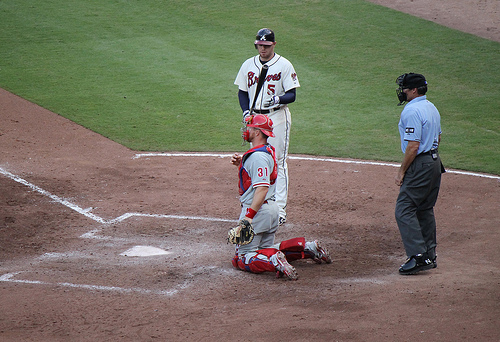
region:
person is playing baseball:
[226, 23, 305, 127]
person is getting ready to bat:
[241, 17, 301, 122]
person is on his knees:
[222, 110, 313, 282]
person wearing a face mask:
[241, 116, 263, 140]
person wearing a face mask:
[383, 62, 413, 105]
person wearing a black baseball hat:
[253, 27, 280, 51]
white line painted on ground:
[8, 153, 121, 228]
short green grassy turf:
[123, 66, 178, 106]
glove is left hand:
[233, 197, 256, 247]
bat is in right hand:
[240, 58, 264, 126]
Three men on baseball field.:
[222, 23, 454, 283]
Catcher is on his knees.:
[221, 108, 333, 285]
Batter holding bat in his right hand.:
[231, 20, 303, 112]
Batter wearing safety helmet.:
[250, 25, 283, 55]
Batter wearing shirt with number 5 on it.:
[228, 26, 303, 111]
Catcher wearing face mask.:
[236, 112, 278, 143]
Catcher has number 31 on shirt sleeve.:
[233, 111, 278, 224]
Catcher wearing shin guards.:
[222, 108, 324, 280]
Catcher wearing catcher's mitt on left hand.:
[224, 107, 306, 244]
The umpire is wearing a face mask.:
[383, 67, 445, 160]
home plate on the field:
[118, 236, 176, 261]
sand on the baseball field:
[20, 152, 430, 337]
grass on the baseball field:
[7, 0, 482, 170]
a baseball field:
[5, 1, 490, 331]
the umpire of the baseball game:
[387, 67, 437, 268]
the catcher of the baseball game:
[225, 107, 305, 277]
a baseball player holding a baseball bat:
[246, 25, 291, 155]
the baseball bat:
[247, 65, 272, 110]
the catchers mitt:
[227, 218, 259, 246]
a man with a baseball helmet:
[251, 25, 271, 45]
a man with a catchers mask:
[390, 70, 410, 102]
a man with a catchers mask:
[235, 110, 250, 140]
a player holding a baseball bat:
[231, 23, 298, 228]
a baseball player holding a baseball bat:
[231, 27, 301, 229]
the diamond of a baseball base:
[117, 240, 172, 260]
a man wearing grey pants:
[386, 145, 441, 256]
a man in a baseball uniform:
[233, 50, 298, 216]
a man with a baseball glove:
[228, 218, 257, 248]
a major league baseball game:
[9, 6, 494, 326]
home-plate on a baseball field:
[118, 236, 172, 263]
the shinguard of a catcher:
[236, 255, 273, 282]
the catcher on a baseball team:
[211, 114, 328, 282]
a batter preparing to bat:
[219, 15, 300, 111]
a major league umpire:
[370, 63, 471, 286]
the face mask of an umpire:
[391, 65, 430, 107]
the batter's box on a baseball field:
[91, 204, 237, 243]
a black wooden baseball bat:
[250, 59, 268, 111]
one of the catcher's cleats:
[270, 245, 305, 284]